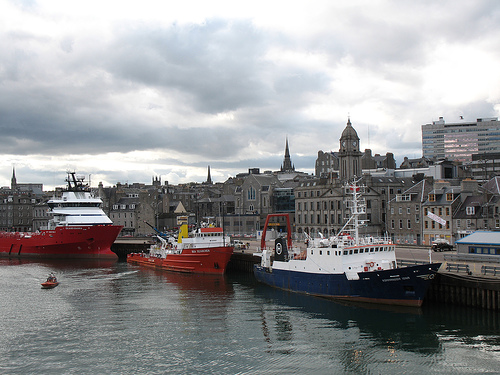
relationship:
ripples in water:
[64, 313, 234, 373] [0, 249, 498, 372]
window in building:
[6, 121, 498, 243] [232, 166, 313, 252]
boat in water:
[9, 162, 442, 326] [0, 249, 498, 372]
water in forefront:
[0, 249, 498, 372] [4, 258, 499, 371]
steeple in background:
[0, 249, 498, 372] [272, 131, 302, 174]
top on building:
[337, 115, 365, 147] [0, 115, 499, 277]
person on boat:
[43, 269, 63, 282] [9, 162, 442, 326]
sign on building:
[423, 208, 460, 234] [0, 115, 499, 277]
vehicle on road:
[9, 162, 442, 326] [220, 222, 498, 274]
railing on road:
[396, 245, 494, 277] [227, 231, 497, 286]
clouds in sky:
[3, 3, 496, 169] [5, 0, 499, 159]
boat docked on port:
[9, 162, 442, 326] [170, 228, 498, 304]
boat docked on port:
[9, 162, 442, 326] [142, 218, 496, 316]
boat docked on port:
[9, 162, 442, 326] [195, 211, 497, 312]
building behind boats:
[0, 115, 499, 277] [10, 176, 449, 311]